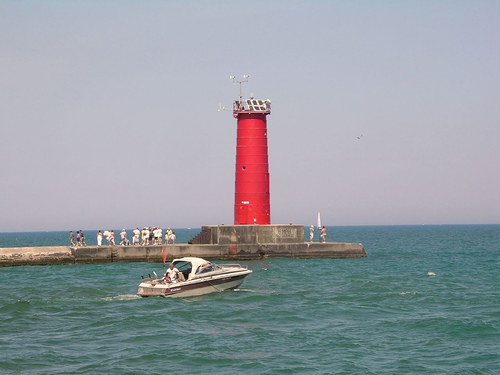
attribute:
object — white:
[312, 209, 325, 229]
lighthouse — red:
[229, 93, 283, 228]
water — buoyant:
[1, 230, 498, 372]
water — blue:
[16, 231, 478, 348]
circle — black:
[241, 166, 245, 173]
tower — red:
[208, 87, 302, 232]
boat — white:
[131, 253, 260, 301]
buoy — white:
[424, 268, 436, 277]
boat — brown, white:
[135, 252, 253, 302]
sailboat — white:
[316, 209, 323, 230]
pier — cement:
[12, 241, 369, 264]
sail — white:
[317, 213, 322, 233]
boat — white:
[136, 256, 253, 301]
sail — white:
[314, 211, 324, 227]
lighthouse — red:
[231, 97, 274, 222]